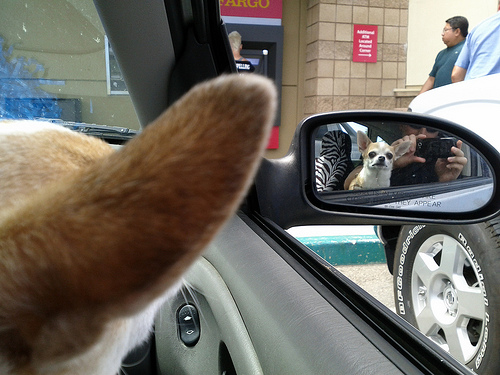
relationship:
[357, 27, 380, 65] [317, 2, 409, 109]
sign on a wall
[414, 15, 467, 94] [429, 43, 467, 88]
man in shirt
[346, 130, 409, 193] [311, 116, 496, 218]
dog in mirror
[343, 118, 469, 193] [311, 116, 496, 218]
person in mirror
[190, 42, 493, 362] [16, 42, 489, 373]
window in car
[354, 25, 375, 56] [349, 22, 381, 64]
lettering on sign